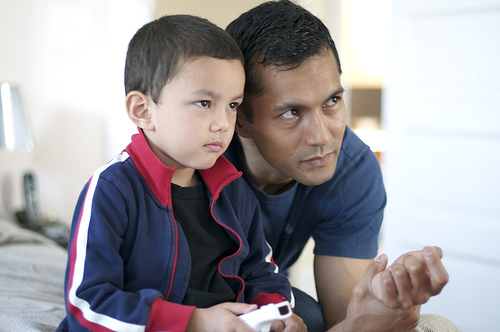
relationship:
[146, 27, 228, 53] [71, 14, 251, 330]
brunette young child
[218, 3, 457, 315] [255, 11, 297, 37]
man haired black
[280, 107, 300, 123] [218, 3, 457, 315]
eye of a man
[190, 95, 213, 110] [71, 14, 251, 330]
eye of a boy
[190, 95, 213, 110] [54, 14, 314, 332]
eye of a child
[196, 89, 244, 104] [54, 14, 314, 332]
eyebrow of a child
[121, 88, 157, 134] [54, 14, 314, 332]
ear of a child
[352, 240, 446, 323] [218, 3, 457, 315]
hand of a man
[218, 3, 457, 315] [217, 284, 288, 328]
man playing wii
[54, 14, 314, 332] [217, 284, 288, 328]
child play wii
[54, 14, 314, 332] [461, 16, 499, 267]
child staring at tv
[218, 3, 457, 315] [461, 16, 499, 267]
man staring at tv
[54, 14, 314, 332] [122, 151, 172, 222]
child in blue and red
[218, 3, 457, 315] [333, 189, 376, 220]
man in blue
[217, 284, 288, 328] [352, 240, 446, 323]
wii in hand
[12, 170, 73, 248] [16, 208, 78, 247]
telephone in its handset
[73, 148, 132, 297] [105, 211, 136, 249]
stripe on blue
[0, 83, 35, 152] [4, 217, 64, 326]
lampshade next to bed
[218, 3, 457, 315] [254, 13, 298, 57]
man has hair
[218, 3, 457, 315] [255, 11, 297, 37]
man hair black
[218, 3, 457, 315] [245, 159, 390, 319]
man wearing a shirt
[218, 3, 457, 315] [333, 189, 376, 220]
man shirt blue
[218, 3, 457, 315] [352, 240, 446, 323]
man holding wrist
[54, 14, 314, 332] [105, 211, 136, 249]
child wearing blue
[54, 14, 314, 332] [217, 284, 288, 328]
child holding remote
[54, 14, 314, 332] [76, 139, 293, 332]
child wearing jacket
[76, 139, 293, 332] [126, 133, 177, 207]
jacket with red trim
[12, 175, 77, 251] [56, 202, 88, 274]
telephone on table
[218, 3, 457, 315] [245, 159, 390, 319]
man wearing shirt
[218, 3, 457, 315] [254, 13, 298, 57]
man with hair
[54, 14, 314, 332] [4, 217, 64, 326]
child sitting on a bed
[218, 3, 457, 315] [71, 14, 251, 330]
man and child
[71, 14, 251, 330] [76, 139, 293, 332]
child wearing a jacket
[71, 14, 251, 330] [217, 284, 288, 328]
child playing wii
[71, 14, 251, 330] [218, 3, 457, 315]
child and man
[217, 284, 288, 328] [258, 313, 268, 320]
wii remote white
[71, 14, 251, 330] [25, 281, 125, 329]
child sitting down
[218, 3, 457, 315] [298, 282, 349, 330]
man sitting down